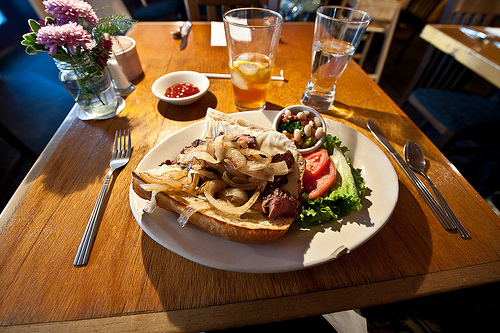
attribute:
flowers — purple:
[20, 0, 133, 75]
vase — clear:
[50, 50, 126, 125]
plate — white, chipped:
[129, 105, 402, 276]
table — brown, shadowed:
[2, 11, 499, 323]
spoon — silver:
[400, 138, 471, 240]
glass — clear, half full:
[220, 9, 280, 110]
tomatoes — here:
[304, 148, 338, 199]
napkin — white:
[211, 18, 249, 44]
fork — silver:
[75, 125, 132, 267]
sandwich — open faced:
[132, 106, 304, 240]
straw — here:
[200, 68, 296, 84]